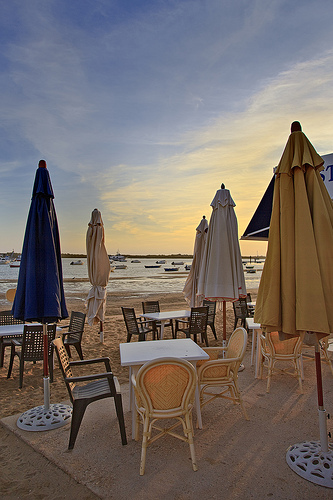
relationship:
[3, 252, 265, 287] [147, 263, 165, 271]
harbor has a boat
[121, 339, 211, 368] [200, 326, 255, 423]
table has chairs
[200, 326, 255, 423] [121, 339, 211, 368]
chairs at table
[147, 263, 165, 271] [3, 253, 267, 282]
boat on water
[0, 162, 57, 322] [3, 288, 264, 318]
umbrella in sand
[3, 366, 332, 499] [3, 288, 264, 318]
patio on sand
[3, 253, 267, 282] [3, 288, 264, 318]
water near sand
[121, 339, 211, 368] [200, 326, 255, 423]
table has a chairs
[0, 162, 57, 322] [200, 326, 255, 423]
umbrella next to chairs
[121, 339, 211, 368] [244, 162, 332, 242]
table next to tent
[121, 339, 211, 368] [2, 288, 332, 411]
table at beach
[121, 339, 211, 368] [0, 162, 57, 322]
table has a umbrella